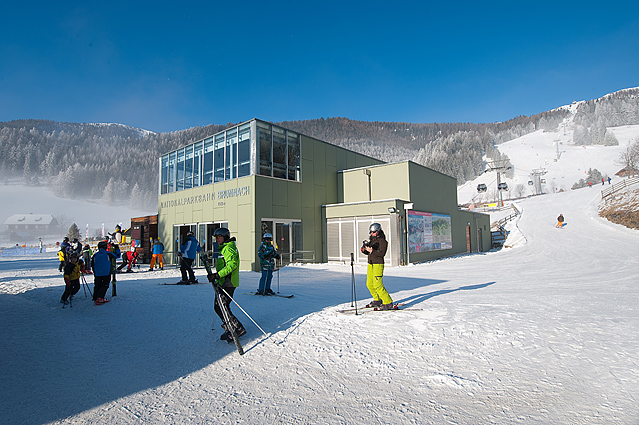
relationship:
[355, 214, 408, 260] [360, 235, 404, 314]
person in ski gear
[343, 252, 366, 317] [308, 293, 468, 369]
ski poles stuck in snow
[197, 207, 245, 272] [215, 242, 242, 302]
person in coat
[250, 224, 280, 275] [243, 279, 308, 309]
person using skis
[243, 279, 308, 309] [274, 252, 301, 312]
skis and ski poles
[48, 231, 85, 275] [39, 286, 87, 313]
person using ski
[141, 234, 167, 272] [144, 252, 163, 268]
person wearing pants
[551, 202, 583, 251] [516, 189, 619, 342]
person skiing hill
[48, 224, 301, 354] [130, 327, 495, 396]
skiiers standing snow